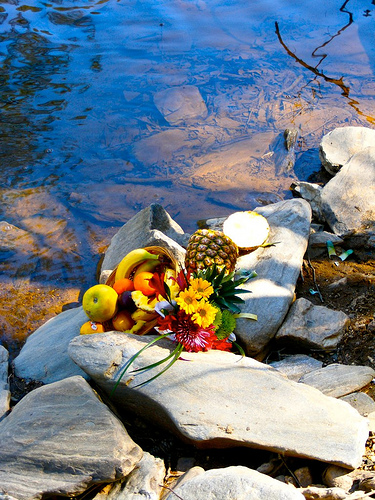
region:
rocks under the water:
[139, 53, 282, 177]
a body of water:
[8, 3, 340, 206]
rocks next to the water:
[265, 144, 372, 255]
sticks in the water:
[225, 49, 303, 134]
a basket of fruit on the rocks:
[69, 212, 174, 371]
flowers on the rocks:
[161, 277, 229, 360]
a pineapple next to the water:
[186, 220, 281, 278]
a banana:
[107, 244, 160, 278]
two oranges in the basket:
[111, 269, 162, 293]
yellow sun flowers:
[181, 277, 214, 323]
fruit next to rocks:
[102, 208, 242, 351]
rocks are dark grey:
[233, 204, 296, 326]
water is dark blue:
[110, 65, 174, 141]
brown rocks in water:
[148, 88, 264, 194]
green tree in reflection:
[0, 7, 90, 166]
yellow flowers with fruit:
[173, 265, 227, 332]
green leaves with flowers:
[107, 335, 190, 397]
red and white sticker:
[68, 314, 107, 342]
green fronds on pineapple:
[195, 245, 244, 309]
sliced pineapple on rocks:
[182, 222, 274, 288]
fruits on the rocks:
[75, 206, 273, 354]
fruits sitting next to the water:
[70, 207, 273, 342]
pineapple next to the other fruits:
[180, 209, 271, 281]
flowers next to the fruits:
[172, 275, 220, 331]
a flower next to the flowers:
[177, 284, 201, 315]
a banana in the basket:
[111, 247, 161, 282]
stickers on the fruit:
[88, 320, 100, 330]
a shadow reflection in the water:
[309, 0, 363, 72]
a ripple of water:
[25, 30, 121, 60]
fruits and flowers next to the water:
[74, 204, 278, 399]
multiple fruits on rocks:
[66, 153, 309, 448]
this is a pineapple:
[178, 199, 284, 289]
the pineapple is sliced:
[178, 205, 289, 300]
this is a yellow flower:
[173, 267, 228, 335]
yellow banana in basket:
[107, 234, 162, 292]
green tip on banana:
[144, 243, 164, 267]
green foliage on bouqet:
[96, 311, 194, 394]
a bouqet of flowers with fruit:
[112, 260, 257, 400]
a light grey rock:
[84, 318, 371, 475]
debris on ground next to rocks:
[311, 211, 365, 333]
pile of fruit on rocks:
[79, 208, 272, 361]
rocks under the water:
[1, 84, 355, 270]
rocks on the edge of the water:
[5, 126, 371, 426]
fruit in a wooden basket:
[103, 243, 184, 334]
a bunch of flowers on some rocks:
[119, 264, 240, 389]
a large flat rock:
[71, 330, 372, 472]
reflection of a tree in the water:
[3, 2, 103, 190]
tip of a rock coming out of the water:
[269, 127, 301, 166]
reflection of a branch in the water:
[273, 2, 371, 123]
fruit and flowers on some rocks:
[79, 211, 274, 365]